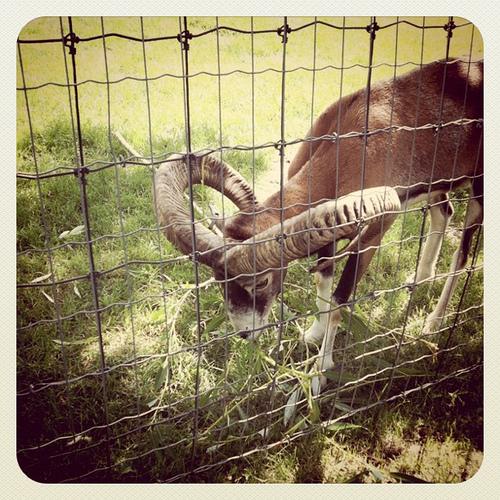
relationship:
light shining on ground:
[269, 395, 472, 480] [26, 31, 470, 478]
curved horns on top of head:
[152, 153, 401, 276] [209, 211, 291, 331]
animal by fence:
[152, 56, 484, 395] [16, 15, 483, 483]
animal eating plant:
[152, 56, 484, 395] [171, 304, 417, 496]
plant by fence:
[171, 304, 417, 496] [16, 15, 483, 483]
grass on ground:
[19, 19, 491, 488] [26, 31, 470, 478]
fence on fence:
[16, 16, 484, 484] [16, 15, 483, 483]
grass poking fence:
[16, 16, 484, 485] [79, 240, 157, 314]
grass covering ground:
[16, 16, 484, 485] [26, 31, 470, 478]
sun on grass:
[164, 53, 226, 86] [42, 27, 344, 122]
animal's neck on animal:
[221, 168, 358, 235] [140, 50, 484, 387]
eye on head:
[250, 277, 268, 292] [152, 150, 395, 342]